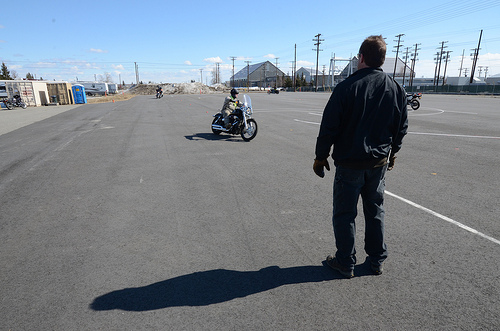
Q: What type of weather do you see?
A: It is cloudy.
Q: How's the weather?
A: It is cloudy.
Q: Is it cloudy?
A: Yes, it is cloudy.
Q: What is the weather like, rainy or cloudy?
A: It is cloudy.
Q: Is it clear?
A: No, it is cloudy.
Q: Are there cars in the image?
A: No, there are no cars.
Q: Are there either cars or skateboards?
A: No, there are no cars or skateboards.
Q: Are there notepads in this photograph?
A: No, there are no notepads.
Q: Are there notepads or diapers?
A: No, there are no notepads or diapers.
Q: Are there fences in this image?
A: No, there are no fences.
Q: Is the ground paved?
A: Yes, the ground is paved.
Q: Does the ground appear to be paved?
A: Yes, the ground is paved.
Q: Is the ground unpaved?
A: No, the ground is paved.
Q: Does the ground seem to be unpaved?
A: No, the ground is paved.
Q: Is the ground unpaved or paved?
A: The ground is paved.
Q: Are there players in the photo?
A: No, there are no players.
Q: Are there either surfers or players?
A: No, there are no players or surfers.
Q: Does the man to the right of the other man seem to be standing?
A: Yes, the man is standing.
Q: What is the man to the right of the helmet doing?
A: The man is standing.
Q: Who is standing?
A: The man is standing.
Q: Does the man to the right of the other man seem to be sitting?
A: No, the man is standing.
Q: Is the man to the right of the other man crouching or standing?
A: The man is standing.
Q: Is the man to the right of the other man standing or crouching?
A: The man is standing.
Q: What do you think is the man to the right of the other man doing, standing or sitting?
A: The man is standing.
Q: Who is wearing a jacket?
A: The man is wearing a jacket.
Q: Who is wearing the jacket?
A: The man is wearing a jacket.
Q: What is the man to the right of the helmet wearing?
A: The man is wearing a jacket.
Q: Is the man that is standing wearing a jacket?
A: Yes, the man is wearing a jacket.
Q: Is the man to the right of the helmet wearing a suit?
A: No, the man is wearing a jacket.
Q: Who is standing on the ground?
A: The man is standing on the ground.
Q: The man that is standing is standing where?
A: The man is standing on the ground.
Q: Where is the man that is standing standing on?
A: The man is standing on the ground.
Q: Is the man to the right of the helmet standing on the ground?
A: Yes, the man is standing on the ground.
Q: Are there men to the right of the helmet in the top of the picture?
A: Yes, there is a man to the right of the helmet.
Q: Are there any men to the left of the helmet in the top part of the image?
A: No, the man is to the right of the helmet.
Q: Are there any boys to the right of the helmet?
A: No, there is a man to the right of the helmet.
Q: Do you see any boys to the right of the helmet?
A: No, there is a man to the right of the helmet.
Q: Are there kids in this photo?
A: No, there are no kids.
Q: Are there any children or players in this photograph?
A: No, there are no children or players.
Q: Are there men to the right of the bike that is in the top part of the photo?
A: Yes, there is a man to the right of the bike.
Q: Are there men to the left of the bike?
A: No, the man is to the right of the bike.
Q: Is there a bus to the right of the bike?
A: No, there is a man to the right of the bike.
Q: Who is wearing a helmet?
A: The man is wearing a helmet.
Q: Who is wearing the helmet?
A: The man is wearing a helmet.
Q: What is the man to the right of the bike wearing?
A: The man is wearing a helmet.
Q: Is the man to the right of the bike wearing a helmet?
A: Yes, the man is wearing a helmet.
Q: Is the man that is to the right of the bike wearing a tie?
A: No, the man is wearing a helmet.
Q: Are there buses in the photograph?
A: No, there are no buses.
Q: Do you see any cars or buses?
A: No, there are no buses or cars.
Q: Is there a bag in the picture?
A: No, there are no bags.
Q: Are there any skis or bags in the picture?
A: No, there are no bags or skis.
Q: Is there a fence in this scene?
A: No, there are no fences.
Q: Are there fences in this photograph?
A: No, there are no fences.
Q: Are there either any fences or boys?
A: No, there are no fences or boys.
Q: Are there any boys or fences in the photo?
A: No, there are no fences or boys.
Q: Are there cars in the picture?
A: No, there are no cars.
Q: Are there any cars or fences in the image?
A: No, there are no cars or fences.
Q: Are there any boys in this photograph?
A: No, there are no boys.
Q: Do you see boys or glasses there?
A: No, there are no boys or glasses.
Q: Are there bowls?
A: No, there are no bowls.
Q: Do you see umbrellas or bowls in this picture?
A: No, there are no bowls or umbrellas.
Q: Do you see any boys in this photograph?
A: No, there are no boys.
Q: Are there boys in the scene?
A: No, there are no boys.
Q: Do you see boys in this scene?
A: No, there are no boys.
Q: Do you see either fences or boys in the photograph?
A: No, there are no boys or fences.